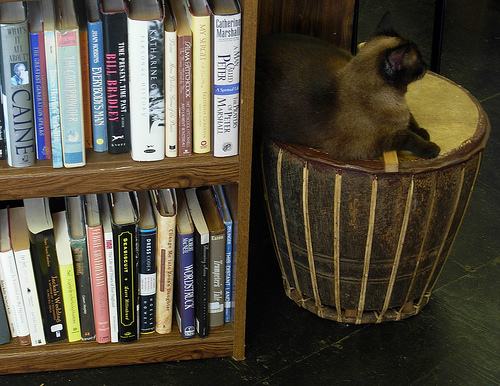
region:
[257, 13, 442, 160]
tan cat sitting on drum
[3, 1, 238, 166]
books on bookshelf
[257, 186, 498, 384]
black wooden floor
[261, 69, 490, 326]
brown and tan drum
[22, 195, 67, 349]
black paperback book on shelf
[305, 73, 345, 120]
black spot on back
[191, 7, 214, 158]
yellow hard cover book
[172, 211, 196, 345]
dark blue hard cover book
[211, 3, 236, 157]
book on book shelf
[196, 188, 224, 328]
book on book shelf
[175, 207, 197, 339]
book on book shelf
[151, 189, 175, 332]
book on book shelf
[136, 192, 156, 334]
book on book shelf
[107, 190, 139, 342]
book on book shelf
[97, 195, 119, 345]
book on book shelf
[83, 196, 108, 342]
book on book shelf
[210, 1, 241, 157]
book next to book on shelf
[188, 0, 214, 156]
book next to book on shelf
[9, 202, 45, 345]
book next to book on shelf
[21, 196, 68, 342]
book next to book on shelf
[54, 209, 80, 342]
book next to book on shelf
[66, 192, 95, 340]
book next to book on shelf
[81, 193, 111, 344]
book next to book on shelf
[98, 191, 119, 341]
book next to book on shelf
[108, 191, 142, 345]
book next to book on shelf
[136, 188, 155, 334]
book next to book on shelf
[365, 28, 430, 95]
head of a cat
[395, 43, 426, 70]
ear of a cat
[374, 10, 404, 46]
ear of a cat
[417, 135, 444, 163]
paw of a cat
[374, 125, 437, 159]
leg of a cat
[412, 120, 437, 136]
paw of a cat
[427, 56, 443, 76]
whisker of a cat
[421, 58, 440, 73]
nose of a cat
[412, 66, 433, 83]
mouth of a cat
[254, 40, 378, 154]
body of a cat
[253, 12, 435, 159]
A cat lying on a drum.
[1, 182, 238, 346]
Books on a bookshelf.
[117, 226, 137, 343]
Spine of a black book.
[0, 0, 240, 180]
Several books on a shelf.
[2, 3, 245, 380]
A wooden bookcase filled with books.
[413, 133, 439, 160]
A cat's black paw.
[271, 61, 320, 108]
Dark gray fur on a cat.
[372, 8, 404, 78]
Ears on a cat's head.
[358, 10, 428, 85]
Back of a cat's head.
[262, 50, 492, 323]
A drum with a cat on top.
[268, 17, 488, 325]
black cat laying on drum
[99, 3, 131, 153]
book with black cover and pink writing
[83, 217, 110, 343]
book with peach cover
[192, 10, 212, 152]
book with yellow cover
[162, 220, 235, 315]
a book on the shelf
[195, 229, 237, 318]
a book on the shelf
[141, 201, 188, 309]
a book on the shelf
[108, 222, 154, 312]
a book on the shelf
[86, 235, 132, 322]
a book on the shelf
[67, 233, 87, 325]
a book on the shelf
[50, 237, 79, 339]
a book on the shelf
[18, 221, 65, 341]
a book on the shelf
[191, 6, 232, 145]
a book on the shelf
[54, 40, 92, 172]
a book on the shelf